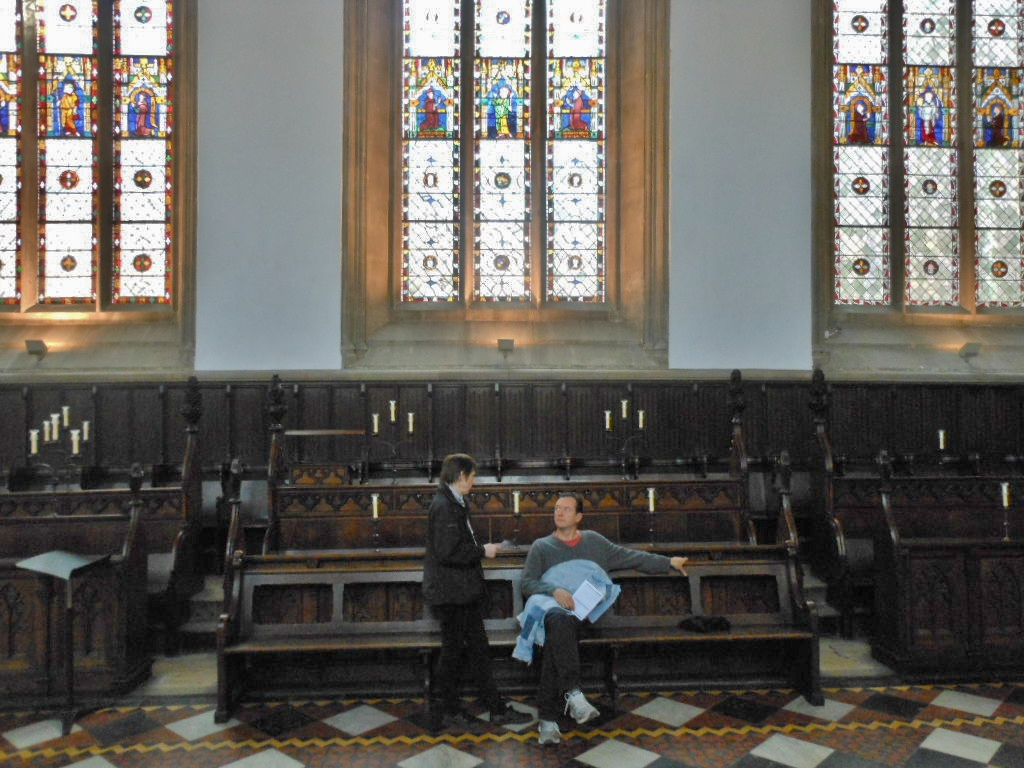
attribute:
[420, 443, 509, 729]
man — standing, talking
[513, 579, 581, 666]
jacket — blue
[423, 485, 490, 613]
jacket — black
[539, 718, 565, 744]
shoe — white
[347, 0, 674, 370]
window — painted